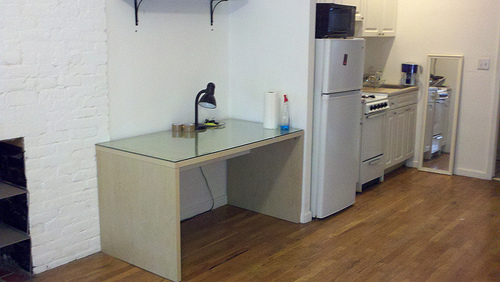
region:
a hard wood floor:
[345, 153, 497, 256]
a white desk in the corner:
[97, 103, 305, 278]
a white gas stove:
[356, 85, 396, 197]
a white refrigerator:
[317, 31, 364, 221]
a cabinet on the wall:
[364, 10, 414, 52]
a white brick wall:
[20, 36, 93, 114]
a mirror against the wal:
[416, 53, 473, 177]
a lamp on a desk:
[186, 81, 225, 132]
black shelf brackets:
[128, 0, 228, 39]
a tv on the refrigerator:
[321, 2, 366, 52]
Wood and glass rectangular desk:
[95, 115, 302, 280]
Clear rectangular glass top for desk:
[96, 117, 308, 161]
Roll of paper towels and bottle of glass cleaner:
[259, 88, 293, 132]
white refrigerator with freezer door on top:
[316, 37, 359, 219]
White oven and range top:
[355, 91, 389, 192]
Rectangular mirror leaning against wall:
[420, 52, 462, 174]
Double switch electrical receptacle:
[473, 57, 492, 71]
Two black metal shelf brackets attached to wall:
[128, 1, 230, 27]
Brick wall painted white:
[28, 77, 101, 268]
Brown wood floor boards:
[366, 194, 483, 275]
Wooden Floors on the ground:
[390, 177, 498, 275]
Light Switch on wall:
[473, 46, 492, 88]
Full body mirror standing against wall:
[419, 50, 461, 175]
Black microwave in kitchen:
[310, 0, 358, 36]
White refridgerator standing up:
[315, 40, 367, 220]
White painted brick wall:
[37, 8, 97, 266]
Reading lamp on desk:
[188, 76, 223, 134]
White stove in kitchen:
[358, 93, 391, 198]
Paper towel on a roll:
[264, 81, 282, 138]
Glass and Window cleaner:
[278, 92, 296, 138]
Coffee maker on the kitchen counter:
[477, 70, 499, 105]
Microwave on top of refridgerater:
[373, 2, 431, 48]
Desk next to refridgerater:
[112, 132, 369, 281]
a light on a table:
[60, 44, 340, 240]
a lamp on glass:
[157, 51, 268, 156]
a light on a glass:
[157, 72, 289, 166]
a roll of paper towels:
[249, 58, 308, 145]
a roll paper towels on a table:
[237, 76, 329, 158]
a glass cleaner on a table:
[218, 87, 348, 179]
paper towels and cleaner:
[211, 77, 294, 160]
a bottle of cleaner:
[227, 77, 346, 155]